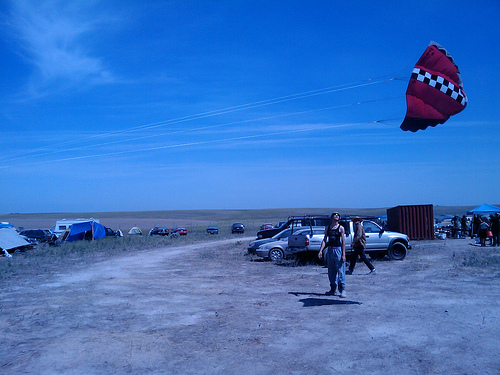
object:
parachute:
[400, 39, 467, 133]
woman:
[318, 212, 347, 298]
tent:
[0, 223, 37, 258]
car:
[255, 227, 326, 261]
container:
[385, 204, 435, 240]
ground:
[0, 206, 499, 374]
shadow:
[298, 297, 363, 307]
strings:
[0, 122, 370, 170]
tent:
[62, 220, 119, 243]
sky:
[0, 0, 498, 213]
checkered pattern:
[411, 68, 468, 108]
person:
[345, 215, 377, 276]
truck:
[287, 218, 411, 263]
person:
[451, 213, 462, 239]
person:
[459, 214, 468, 235]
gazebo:
[467, 203, 500, 239]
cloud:
[8, 0, 113, 102]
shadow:
[288, 292, 346, 298]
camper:
[54, 219, 100, 238]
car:
[247, 226, 325, 255]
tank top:
[326, 224, 342, 248]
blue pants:
[327, 246, 347, 292]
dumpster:
[386, 204, 435, 241]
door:
[351, 220, 389, 250]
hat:
[351, 216, 363, 222]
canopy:
[466, 203, 499, 215]